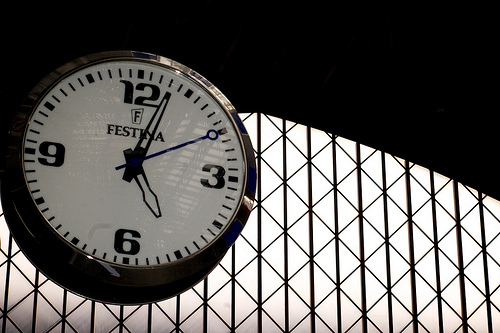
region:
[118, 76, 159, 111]
Numbers on a clock's face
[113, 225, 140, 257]
Number on a clock's face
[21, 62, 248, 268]
A clock's white face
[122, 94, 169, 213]
Minute and hour hands on a clock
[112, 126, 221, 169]
Second hand of a clock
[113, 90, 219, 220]
The hands on a clock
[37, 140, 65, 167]
A number on the clock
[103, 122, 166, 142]
A word on the clock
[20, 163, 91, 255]
Small lines on a clock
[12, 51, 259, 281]
Black numbers on a white clock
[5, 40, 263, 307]
round white clock face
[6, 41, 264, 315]
clock in silver casing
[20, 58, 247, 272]
white clock face with black numbers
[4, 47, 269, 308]
clock that read three past five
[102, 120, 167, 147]
FESTIVA in black letters on clock face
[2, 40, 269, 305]
clock hanging on metal grate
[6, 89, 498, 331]
metal grate wall behind clock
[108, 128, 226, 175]
second hand on clock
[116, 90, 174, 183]
minute hand on clock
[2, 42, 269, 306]
silver casing on clock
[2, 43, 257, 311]
silver clock with white face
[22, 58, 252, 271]
round white clock face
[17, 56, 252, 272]
black numbers on clock face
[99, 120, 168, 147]
FESTIVA on clock face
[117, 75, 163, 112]
number 12 on clock face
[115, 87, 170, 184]
black minute hand on clock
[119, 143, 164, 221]
black hour hand on clock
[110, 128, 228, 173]
black second hand on clock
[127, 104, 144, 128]
letter F in black on clock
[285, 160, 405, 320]
vertical lines through diamond pattern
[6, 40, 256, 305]
deep frame around clock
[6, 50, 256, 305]
black frame, hands, lines and numbers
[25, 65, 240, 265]
white clock face showing time as 5:03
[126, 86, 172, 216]
borders of clock hands with empty interior space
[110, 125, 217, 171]
second hand a straight line ending with circle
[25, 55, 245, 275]
four numbers evenly spaced on top, bottom and sides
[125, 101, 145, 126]
capital letter in four-sided box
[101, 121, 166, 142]
hand covering name of clock manufacturer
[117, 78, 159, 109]
the number twelve is black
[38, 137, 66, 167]
the number nine is black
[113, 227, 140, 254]
the number six is black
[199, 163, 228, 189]
the number three is black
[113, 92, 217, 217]
the clock hands are black and white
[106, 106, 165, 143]
brand name on the clock face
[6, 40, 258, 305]
a large clock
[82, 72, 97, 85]
hour line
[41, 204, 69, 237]
minute lines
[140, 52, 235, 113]
reflection on the rim of the clock